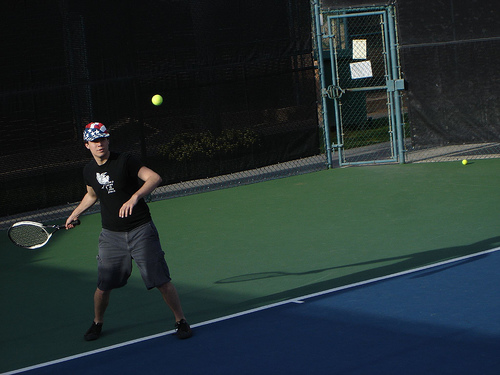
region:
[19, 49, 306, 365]
man in an American Flag hat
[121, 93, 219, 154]
a flying tennis ball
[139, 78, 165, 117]
a small yellowish green ball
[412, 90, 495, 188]
a tennis ball on ground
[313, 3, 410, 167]
poles around chain link fence door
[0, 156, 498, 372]
blue and green tennis court surface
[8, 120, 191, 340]
tennis player with racket in hand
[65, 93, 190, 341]
yellow tennis ball above player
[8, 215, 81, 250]
hand on black grip of racket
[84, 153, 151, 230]
black short sleeve shirt with white emblem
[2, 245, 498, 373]
white boundary line on court surface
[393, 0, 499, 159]
dark fabric covering chain link fence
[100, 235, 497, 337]
shadow of player on tennis court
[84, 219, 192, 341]
gray shorts and black shoes on player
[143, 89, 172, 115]
Ball in the air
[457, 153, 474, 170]
tennis ball on the ground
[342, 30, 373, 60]
white paper attached to the fence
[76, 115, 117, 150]
Man wearing a red, white and blue hat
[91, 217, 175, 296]
man wearing gray shorts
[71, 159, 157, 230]
man wearing a black tee shirts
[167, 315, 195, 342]
man wearing black shoes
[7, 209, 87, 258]
man holding a tennis racket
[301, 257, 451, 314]
white line on the tennis court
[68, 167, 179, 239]
man wearing a black shirt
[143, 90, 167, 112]
Tennis ball in the air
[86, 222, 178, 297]
man wearing a grey shorts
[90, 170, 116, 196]
logo on the t shirt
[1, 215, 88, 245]
man swinging a tennis racket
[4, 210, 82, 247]
man holding a tennis racket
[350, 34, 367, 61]
Paper tag on the fence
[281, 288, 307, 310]
white shadow on the tennis court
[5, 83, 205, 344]
a person playing tennis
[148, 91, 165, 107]
a yellow tennis ball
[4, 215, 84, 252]
a tennis racket the guy is holding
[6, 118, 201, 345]
a guy wearing shorts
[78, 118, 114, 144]
a hat the guy is wearing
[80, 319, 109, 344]
a shoe the guy is wearing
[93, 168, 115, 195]
a print on the guy's shirt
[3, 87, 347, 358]
a guy in the tennis court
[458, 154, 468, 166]
yellow ball on the tennis court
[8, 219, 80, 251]
Black and white tennis racket.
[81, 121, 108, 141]
Red,white and blue hat.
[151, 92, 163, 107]
Yellow tennis ball.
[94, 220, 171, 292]
Dark grey shorts.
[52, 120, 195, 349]
man standing on the blue tennis court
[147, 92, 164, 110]
green tennis ball in the air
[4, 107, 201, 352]
A man playing tennis on a court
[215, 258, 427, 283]
A shadow on the court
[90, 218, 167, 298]
Blue denim shorts on a tennis player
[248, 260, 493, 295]
A white line painted on a tennis court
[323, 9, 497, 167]
A chain link fence with a gate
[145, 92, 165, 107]
A yellow tennis ball in midair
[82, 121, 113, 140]
An American flag baseball cap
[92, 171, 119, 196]
A design on the front of a black shirt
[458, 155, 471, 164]
A yellow tennis ball lying against a fence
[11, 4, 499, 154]
A building behind a tennis court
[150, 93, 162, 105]
tennis ball in mid air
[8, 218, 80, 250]
white and black tennis racquet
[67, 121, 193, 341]
man playing tennis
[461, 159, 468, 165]
tennis ball on the ground